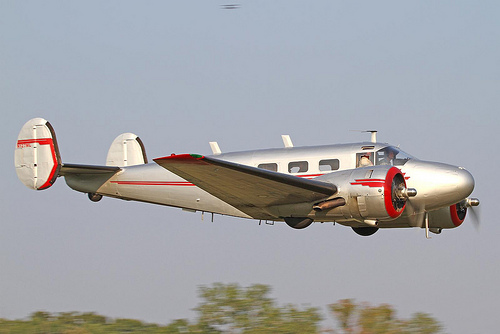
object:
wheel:
[284, 217, 314, 229]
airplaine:
[13, 117, 478, 237]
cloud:
[7, 255, 49, 297]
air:
[0, 14, 499, 112]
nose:
[402, 157, 475, 212]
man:
[356, 152, 374, 167]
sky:
[194, 34, 380, 78]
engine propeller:
[464, 197, 480, 208]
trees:
[0, 281, 443, 333]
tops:
[188, 276, 356, 333]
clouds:
[168, 14, 354, 81]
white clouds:
[403, 42, 464, 107]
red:
[350, 167, 410, 218]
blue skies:
[0, 0, 500, 334]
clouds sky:
[320, 250, 464, 287]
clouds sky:
[264, 22, 441, 98]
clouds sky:
[12, 7, 237, 104]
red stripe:
[110, 181, 193, 187]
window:
[319, 159, 340, 171]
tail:
[13, 117, 62, 190]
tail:
[105, 132, 149, 167]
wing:
[152, 153, 338, 219]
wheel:
[352, 228, 379, 236]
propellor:
[396, 188, 416, 200]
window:
[356, 152, 374, 168]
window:
[362, 146, 375, 150]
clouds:
[179, 44, 322, 119]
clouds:
[135, 44, 251, 126]